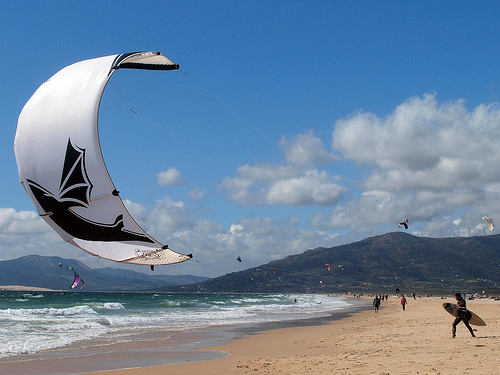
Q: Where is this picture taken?
A: Beach.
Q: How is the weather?
A: Clear.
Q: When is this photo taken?
A: Summer day.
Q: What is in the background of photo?
A: Mountains.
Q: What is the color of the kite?
A: White and black.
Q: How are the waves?
A: Crashing near the shore.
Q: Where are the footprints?
A: The sand.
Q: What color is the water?
A: Blue.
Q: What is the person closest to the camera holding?
A: Surfboard.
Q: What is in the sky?
A: Kites.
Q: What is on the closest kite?
A: A dolphin.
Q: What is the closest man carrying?
A: A surfboard.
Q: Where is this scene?
A: At the beach.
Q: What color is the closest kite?
A: Black and white.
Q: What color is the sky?
A: Blue.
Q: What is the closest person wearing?
A: A wetsuit.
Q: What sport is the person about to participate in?
A: Surfing.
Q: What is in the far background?
A: A mountain range.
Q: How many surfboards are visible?
A: One.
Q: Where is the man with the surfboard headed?
A: Into the water.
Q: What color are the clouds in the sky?
A: White.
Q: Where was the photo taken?
A: On the beach.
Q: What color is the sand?
A: Tan.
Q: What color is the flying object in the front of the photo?
A: Black and white.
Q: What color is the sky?
A: Blue and white.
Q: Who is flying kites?
A: People at the beach.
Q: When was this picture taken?
A: During the day.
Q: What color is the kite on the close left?
A: White and black.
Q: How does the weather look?
A: Bright and sunny.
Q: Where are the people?
A: In the sand.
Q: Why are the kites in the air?
A: People are flying them.